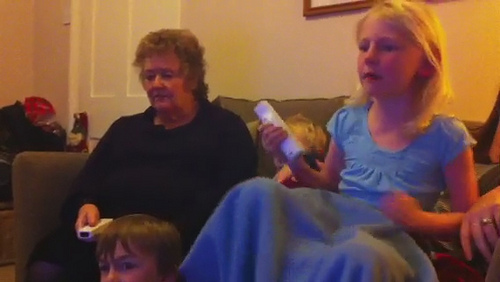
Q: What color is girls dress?
A: Blue.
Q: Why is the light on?
A: To see.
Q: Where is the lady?
A: On couch.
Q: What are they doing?
A: Playing game.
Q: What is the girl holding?
A: Remote.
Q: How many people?
A: 4.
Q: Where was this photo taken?
A: In a living room.